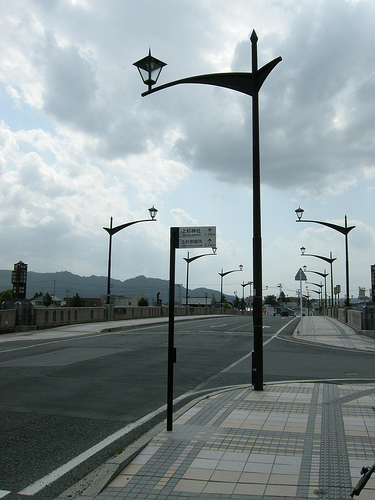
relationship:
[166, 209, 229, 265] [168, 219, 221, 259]
back view of sign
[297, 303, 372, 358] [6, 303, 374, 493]
crosswalk to cross street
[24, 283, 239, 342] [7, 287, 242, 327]
area on other side of bridge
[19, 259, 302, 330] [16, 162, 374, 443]
trees in background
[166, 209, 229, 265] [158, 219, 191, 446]
sign on pole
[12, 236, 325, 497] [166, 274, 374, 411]
intersection of two roads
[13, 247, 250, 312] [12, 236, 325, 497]
mountains in distance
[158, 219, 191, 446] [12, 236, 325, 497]
pole in street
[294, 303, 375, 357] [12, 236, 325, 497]
crosswalk next to street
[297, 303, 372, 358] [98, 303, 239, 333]
curb has pushed up section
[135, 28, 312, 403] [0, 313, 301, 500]
lights by side of pavement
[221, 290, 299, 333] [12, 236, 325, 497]
cars go down on street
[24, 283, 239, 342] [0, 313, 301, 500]
fence on side of pavement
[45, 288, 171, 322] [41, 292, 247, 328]
buildings behind fence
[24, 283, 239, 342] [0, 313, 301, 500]
houses at end of pavement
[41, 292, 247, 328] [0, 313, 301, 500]
fence on side of pavement